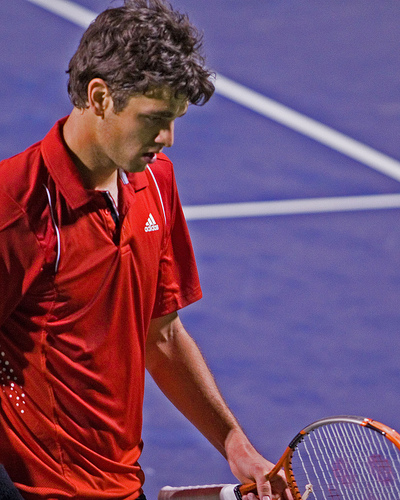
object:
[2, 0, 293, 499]
tennis player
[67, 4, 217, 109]
hair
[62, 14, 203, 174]
head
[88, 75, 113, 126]
ear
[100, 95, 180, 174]
face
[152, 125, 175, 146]
nose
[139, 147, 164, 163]
mouth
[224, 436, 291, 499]
hand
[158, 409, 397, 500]
tennis racket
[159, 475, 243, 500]
handle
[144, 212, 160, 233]
logo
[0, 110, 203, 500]
shirt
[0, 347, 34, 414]
design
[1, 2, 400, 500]
tennis court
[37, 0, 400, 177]
line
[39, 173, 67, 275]
stripe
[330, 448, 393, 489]
design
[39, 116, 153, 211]
collar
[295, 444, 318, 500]
strings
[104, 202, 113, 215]
button